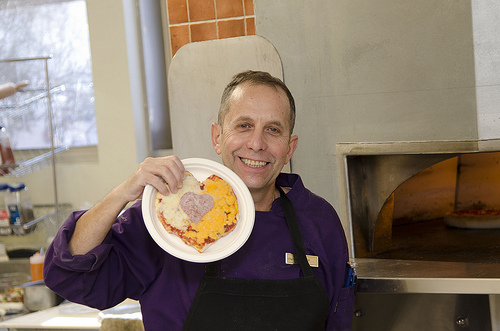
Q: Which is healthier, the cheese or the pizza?
A: The cheese is healthier than the pizza.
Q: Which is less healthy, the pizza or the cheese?
A: The pizza is less healthy than the cheese.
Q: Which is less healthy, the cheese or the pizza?
A: The pizza is less healthy than the cheese.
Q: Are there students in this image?
A: No, there are no students.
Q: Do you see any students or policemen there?
A: No, there are no students or policemen.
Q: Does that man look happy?
A: Yes, the man is happy.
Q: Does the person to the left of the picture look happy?
A: Yes, the man is happy.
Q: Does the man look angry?
A: No, the man is happy.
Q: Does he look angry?
A: No, the man is happy.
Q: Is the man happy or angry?
A: The man is happy.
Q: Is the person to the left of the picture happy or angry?
A: The man is happy.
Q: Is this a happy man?
A: Yes, this is a happy man.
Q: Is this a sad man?
A: No, this is a happy man.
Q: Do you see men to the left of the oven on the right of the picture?
A: Yes, there is a man to the left of the oven.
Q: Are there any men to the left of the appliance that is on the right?
A: Yes, there is a man to the left of the oven.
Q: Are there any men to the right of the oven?
A: No, the man is to the left of the oven.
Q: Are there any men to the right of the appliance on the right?
A: No, the man is to the left of the oven.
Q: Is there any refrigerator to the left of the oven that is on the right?
A: No, there is a man to the left of the oven.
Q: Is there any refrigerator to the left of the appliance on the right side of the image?
A: No, there is a man to the left of the oven.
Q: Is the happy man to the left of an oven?
A: Yes, the man is to the left of an oven.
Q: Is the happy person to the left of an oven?
A: Yes, the man is to the left of an oven.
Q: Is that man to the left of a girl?
A: No, the man is to the left of an oven.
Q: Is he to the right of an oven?
A: No, the man is to the left of an oven.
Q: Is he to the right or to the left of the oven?
A: The man is to the left of the oven.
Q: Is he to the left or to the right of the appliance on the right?
A: The man is to the left of the oven.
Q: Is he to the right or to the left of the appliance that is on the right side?
A: The man is to the left of the oven.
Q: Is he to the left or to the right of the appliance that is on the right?
A: The man is to the left of the oven.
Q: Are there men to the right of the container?
A: Yes, there is a man to the right of the container.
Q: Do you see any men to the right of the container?
A: Yes, there is a man to the right of the container.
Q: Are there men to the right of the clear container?
A: Yes, there is a man to the right of the container.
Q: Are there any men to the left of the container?
A: No, the man is to the right of the container.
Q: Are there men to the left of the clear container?
A: No, the man is to the right of the container.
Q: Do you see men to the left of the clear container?
A: No, the man is to the right of the container.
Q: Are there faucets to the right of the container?
A: No, there is a man to the right of the container.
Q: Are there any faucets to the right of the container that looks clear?
A: No, there is a man to the right of the container.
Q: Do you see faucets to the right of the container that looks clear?
A: No, there is a man to the right of the container.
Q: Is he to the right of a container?
A: Yes, the man is to the right of a container.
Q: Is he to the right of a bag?
A: No, the man is to the right of a container.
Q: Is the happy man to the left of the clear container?
A: No, the man is to the right of the container.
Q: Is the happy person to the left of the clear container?
A: No, the man is to the right of the container.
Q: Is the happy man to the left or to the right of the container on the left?
A: The man is to the right of the container.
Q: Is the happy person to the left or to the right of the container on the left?
A: The man is to the right of the container.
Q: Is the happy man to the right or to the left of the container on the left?
A: The man is to the right of the container.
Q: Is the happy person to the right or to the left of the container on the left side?
A: The man is to the right of the container.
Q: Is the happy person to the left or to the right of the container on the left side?
A: The man is to the right of the container.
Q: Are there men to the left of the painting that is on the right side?
A: Yes, there is a man to the left of the painting.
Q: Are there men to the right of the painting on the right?
A: No, the man is to the left of the painting.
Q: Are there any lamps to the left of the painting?
A: No, there is a man to the left of the painting.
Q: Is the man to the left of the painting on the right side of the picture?
A: Yes, the man is to the left of the painting.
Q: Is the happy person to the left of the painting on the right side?
A: Yes, the man is to the left of the painting.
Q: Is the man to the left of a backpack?
A: No, the man is to the left of the painting.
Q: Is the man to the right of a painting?
A: No, the man is to the left of a painting.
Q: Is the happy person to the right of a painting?
A: No, the man is to the left of a painting.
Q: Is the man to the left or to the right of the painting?
A: The man is to the left of the painting.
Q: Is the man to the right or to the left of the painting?
A: The man is to the left of the painting.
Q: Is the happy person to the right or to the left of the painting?
A: The man is to the left of the painting.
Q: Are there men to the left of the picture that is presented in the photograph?
A: Yes, there is a man to the left of the picture.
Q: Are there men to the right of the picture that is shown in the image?
A: No, the man is to the left of the picture.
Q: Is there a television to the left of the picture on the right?
A: No, there is a man to the left of the picture.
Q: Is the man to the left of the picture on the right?
A: Yes, the man is to the left of the picture.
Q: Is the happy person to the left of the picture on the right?
A: Yes, the man is to the left of the picture.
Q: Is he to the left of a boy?
A: No, the man is to the left of the picture.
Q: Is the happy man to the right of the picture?
A: No, the man is to the left of the picture.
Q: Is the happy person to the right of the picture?
A: No, the man is to the left of the picture.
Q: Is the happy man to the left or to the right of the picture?
A: The man is to the left of the picture.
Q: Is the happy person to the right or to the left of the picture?
A: The man is to the left of the picture.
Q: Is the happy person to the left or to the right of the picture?
A: The man is to the left of the picture.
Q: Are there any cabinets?
A: No, there are no cabinets.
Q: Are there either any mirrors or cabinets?
A: No, there are no cabinets or mirrors.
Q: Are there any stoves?
A: No, there are no stoves.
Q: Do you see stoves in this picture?
A: No, there are no stoves.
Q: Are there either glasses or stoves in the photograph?
A: No, there are no stoves or glasses.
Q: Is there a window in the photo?
A: Yes, there is a window.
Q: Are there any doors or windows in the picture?
A: Yes, there is a window.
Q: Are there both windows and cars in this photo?
A: No, there is a window but no cars.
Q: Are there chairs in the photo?
A: No, there are no chairs.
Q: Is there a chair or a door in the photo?
A: No, there are no chairs or doors.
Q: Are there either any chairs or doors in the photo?
A: No, there are no chairs or doors.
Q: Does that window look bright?
A: Yes, the window is bright.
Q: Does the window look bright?
A: Yes, the window is bright.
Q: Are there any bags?
A: No, there are no bags.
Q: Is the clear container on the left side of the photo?
A: Yes, the container is on the left of the image.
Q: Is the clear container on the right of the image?
A: No, the container is on the left of the image.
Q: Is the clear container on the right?
A: No, the container is on the left of the image.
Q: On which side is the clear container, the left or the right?
A: The container is on the left of the image.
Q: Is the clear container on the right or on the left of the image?
A: The container is on the left of the image.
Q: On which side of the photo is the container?
A: The container is on the left of the image.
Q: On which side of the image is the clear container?
A: The container is on the left of the image.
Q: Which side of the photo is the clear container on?
A: The container is on the left of the image.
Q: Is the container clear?
A: Yes, the container is clear.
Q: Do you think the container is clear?
A: Yes, the container is clear.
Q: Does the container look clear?
A: Yes, the container is clear.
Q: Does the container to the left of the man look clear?
A: Yes, the container is clear.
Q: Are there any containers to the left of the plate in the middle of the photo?
A: Yes, there is a container to the left of the plate.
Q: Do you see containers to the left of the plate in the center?
A: Yes, there is a container to the left of the plate.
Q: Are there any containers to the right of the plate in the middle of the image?
A: No, the container is to the left of the plate.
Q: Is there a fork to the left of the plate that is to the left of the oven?
A: No, there is a container to the left of the plate.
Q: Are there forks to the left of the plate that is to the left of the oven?
A: No, there is a container to the left of the plate.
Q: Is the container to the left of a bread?
A: No, the container is to the left of the plate.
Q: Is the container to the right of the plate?
A: No, the container is to the left of the plate.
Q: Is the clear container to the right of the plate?
A: No, the container is to the left of the plate.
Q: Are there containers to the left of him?
A: Yes, there is a container to the left of the man.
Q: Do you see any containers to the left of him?
A: Yes, there is a container to the left of the man.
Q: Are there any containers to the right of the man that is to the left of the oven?
A: No, the container is to the left of the man.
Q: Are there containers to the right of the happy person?
A: No, the container is to the left of the man.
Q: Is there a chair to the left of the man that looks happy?
A: No, there is a container to the left of the man.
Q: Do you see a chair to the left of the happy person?
A: No, there is a container to the left of the man.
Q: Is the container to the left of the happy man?
A: Yes, the container is to the left of the man.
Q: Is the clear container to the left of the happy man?
A: Yes, the container is to the left of the man.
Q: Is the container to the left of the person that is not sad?
A: Yes, the container is to the left of the man.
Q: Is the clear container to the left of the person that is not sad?
A: Yes, the container is to the left of the man.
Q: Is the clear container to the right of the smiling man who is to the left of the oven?
A: No, the container is to the left of the man.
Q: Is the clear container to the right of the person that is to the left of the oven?
A: No, the container is to the left of the man.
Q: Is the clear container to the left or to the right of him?
A: The container is to the left of the man.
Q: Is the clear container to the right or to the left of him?
A: The container is to the left of the man.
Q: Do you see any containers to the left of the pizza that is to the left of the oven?
A: Yes, there is a container to the left of the pizza.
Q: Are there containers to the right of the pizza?
A: No, the container is to the left of the pizza.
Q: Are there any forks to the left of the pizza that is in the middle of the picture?
A: No, there is a container to the left of the pizza.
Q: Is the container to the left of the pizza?
A: Yes, the container is to the left of the pizza.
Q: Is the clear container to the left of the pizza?
A: Yes, the container is to the left of the pizza.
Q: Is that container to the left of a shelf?
A: No, the container is to the left of the pizza.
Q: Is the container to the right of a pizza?
A: No, the container is to the left of a pizza.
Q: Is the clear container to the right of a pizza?
A: No, the container is to the left of a pizza.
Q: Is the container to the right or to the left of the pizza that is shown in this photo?
A: The container is to the left of the pizza.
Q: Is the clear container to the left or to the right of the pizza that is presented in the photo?
A: The container is to the left of the pizza.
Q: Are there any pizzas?
A: Yes, there is a pizza.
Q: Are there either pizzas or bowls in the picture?
A: Yes, there is a pizza.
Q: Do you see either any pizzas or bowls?
A: Yes, there is a pizza.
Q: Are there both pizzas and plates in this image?
A: Yes, there are both a pizza and a plate.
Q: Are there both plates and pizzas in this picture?
A: Yes, there are both a pizza and a plate.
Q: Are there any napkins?
A: No, there are no napkins.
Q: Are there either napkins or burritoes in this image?
A: No, there are no napkins or burritoes.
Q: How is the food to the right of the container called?
A: The food is a pizza.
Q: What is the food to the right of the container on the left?
A: The food is a pizza.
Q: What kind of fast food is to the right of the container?
A: The food is a pizza.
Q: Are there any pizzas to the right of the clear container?
A: Yes, there is a pizza to the right of the container.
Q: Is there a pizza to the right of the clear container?
A: Yes, there is a pizza to the right of the container.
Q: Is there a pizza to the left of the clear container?
A: No, the pizza is to the right of the container.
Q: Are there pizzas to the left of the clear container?
A: No, the pizza is to the right of the container.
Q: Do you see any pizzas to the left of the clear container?
A: No, the pizza is to the right of the container.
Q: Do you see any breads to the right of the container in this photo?
A: No, there is a pizza to the right of the container.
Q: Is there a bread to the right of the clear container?
A: No, there is a pizza to the right of the container.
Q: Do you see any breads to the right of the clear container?
A: No, there is a pizza to the right of the container.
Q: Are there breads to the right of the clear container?
A: No, there is a pizza to the right of the container.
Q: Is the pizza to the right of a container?
A: Yes, the pizza is to the right of a container.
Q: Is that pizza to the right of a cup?
A: No, the pizza is to the right of a container.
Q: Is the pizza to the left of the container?
A: No, the pizza is to the right of the container.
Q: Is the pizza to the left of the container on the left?
A: No, the pizza is to the right of the container.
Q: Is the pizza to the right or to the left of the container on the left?
A: The pizza is to the right of the container.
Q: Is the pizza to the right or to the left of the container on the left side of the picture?
A: The pizza is to the right of the container.